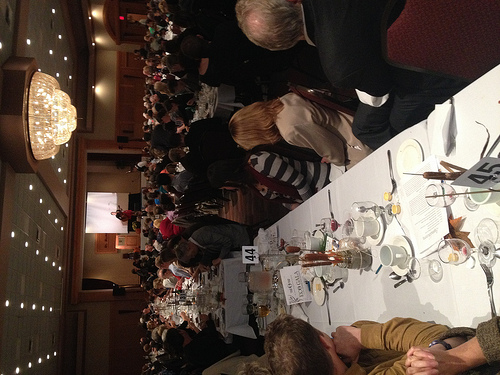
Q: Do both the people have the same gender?
A: No, they are both male and female.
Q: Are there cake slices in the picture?
A: No, there are no cake slices.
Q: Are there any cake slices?
A: No, there are no cake slices.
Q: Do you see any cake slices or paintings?
A: No, there are no cake slices or paintings.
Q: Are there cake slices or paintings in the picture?
A: No, there are no cake slices or paintings.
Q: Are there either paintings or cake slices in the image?
A: No, there are no cake slices or paintings.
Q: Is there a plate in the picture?
A: Yes, there is a plate.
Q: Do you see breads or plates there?
A: Yes, there is a plate.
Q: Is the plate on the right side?
A: Yes, the plate is on the right of the image.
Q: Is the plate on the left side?
A: No, the plate is on the right of the image.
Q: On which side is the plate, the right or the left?
A: The plate is on the right of the image.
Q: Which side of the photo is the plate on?
A: The plate is on the right of the image.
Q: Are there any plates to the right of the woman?
A: Yes, there is a plate to the right of the woman.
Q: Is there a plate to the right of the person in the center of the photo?
A: Yes, there is a plate to the right of the woman.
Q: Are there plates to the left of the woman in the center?
A: No, the plate is to the right of the woman.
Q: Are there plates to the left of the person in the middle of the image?
A: No, the plate is to the right of the woman.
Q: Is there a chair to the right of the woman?
A: No, there is a plate to the right of the woman.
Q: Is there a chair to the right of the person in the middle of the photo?
A: No, there is a plate to the right of the woman.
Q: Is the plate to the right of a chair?
A: No, the plate is to the right of the woman.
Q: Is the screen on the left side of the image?
A: Yes, the screen is on the left of the image.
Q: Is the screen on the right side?
A: No, the screen is on the left of the image.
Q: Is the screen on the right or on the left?
A: The screen is on the left of the image.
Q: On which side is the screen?
A: The screen is on the left of the image.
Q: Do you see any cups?
A: Yes, there is a cup.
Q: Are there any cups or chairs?
A: Yes, there is a cup.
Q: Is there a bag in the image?
A: No, there are no bags.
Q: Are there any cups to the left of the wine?
A: No, the cup is to the right of the wine.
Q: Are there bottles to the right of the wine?
A: No, there is a cup to the right of the wine.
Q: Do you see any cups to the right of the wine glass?
A: Yes, there is a cup to the right of the wine glass.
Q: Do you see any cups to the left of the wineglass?
A: No, the cup is to the right of the wineglass.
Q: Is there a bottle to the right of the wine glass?
A: No, there is a cup to the right of the wine glass.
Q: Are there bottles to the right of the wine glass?
A: No, there is a cup to the right of the wine glass.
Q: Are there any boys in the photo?
A: No, there are no boys.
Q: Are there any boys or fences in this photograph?
A: No, there are no boys or fences.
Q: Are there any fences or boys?
A: No, there are no boys or fences.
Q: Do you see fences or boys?
A: No, there are no boys or fences.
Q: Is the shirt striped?
A: Yes, the shirt is striped.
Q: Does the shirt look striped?
A: Yes, the shirt is striped.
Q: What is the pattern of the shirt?
A: The shirt is striped.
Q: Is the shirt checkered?
A: No, the shirt is striped.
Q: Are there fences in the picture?
A: No, there are no fences.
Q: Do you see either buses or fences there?
A: No, there are no fences or buses.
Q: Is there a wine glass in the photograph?
A: Yes, there is a wine glass.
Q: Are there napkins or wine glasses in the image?
A: Yes, there is a wine glass.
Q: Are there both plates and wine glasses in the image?
A: Yes, there are both a wine glass and a plate.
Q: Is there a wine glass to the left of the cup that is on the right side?
A: Yes, there is a wine glass to the left of the cup.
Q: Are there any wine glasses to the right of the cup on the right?
A: No, the wine glass is to the left of the cup.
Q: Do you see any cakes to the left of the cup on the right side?
A: No, there is a wine glass to the left of the cup.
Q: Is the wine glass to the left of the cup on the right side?
A: Yes, the wine glass is to the left of the cup.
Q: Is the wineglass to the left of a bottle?
A: No, the wineglass is to the left of the cup.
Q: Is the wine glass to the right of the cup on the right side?
A: No, the wine glass is to the left of the cup.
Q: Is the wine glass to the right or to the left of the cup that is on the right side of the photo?
A: The wine glass is to the left of the cup.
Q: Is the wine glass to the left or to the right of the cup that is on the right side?
A: The wine glass is to the left of the cup.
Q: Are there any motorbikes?
A: No, there are no motorbikes.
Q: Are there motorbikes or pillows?
A: No, there are no motorbikes or pillows.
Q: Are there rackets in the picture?
A: No, there are no rackets.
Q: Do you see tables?
A: Yes, there is a table.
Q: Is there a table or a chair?
A: Yes, there is a table.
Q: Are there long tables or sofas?
A: Yes, there is a long table.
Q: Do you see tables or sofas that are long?
A: Yes, the table is long.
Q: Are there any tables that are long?
A: Yes, there is a long table.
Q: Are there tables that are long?
A: Yes, there is a table that is long.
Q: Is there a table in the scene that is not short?
A: Yes, there is a long table.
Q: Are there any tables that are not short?
A: Yes, there is a long table.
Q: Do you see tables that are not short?
A: Yes, there is a long table.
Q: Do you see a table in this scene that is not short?
A: Yes, there is a long table.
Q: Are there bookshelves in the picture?
A: No, there are no bookshelves.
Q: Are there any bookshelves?
A: No, there are no bookshelves.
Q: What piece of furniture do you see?
A: The piece of furniture is a table.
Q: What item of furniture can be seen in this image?
A: The piece of furniture is a table.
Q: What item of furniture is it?
A: The piece of furniture is a table.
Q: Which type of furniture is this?
A: That is a table.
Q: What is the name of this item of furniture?
A: That is a table.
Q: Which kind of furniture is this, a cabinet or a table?
A: That is a table.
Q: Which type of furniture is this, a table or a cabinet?
A: That is a table.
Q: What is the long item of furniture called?
A: The piece of furniture is a table.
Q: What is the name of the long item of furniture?
A: The piece of furniture is a table.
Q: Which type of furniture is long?
A: The furniture is a table.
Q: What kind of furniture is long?
A: The furniture is a table.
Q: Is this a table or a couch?
A: This is a table.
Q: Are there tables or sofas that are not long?
A: No, there is a table but it is long.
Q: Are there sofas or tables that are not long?
A: No, there is a table but it is long.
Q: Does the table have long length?
A: Yes, the table is long.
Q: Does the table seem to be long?
A: Yes, the table is long.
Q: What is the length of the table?
A: The table is long.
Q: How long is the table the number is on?
A: The table is long.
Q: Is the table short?
A: No, the table is long.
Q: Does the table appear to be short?
A: No, the table is long.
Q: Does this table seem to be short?
A: No, the table is long.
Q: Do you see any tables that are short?
A: No, there is a table but it is long.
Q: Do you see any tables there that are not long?
A: No, there is a table but it is long.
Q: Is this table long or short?
A: The table is long.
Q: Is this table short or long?
A: The table is long.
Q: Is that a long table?
A: Yes, that is a long table.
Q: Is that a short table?
A: No, that is a long table.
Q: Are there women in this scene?
A: Yes, there is a woman.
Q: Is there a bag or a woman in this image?
A: Yes, there is a woman.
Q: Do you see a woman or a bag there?
A: Yes, there is a woman.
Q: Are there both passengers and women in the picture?
A: No, there is a woman but no passengers.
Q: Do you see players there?
A: No, there are no players.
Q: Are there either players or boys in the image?
A: No, there are no players or boys.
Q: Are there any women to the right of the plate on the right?
A: No, the woman is to the left of the plate.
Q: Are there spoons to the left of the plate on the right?
A: No, there is a woman to the left of the plate.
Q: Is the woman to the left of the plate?
A: Yes, the woman is to the left of the plate.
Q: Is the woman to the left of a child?
A: No, the woman is to the left of the plate.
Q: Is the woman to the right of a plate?
A: No, the woman is to the left of a plate.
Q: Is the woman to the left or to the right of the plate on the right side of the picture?
A: The woman is to the left of the plate.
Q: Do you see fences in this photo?
A: No, there are no fences.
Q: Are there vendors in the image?
A: No, there are no vendors.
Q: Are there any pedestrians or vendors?
A: No, there are no vendors or pedestrians.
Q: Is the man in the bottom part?
A: Yes, the man is in the bottom of the image.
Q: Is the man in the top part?
A: No, the man is in the bottom of the image.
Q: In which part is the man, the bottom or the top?
A: The man is in the bottom of the image.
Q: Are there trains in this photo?
A: No, there are no trains.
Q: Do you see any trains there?
A: No, there are no trains.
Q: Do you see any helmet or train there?
A: No, there are no trains or helmets.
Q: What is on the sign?
A: The number is on the sign.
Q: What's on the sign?
A: The number is on the sign.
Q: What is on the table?
A: The number is on the table.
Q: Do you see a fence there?
A: No, there are no fences.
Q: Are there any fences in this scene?
A: No, there are no fences.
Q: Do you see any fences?
A: No, there are no fences.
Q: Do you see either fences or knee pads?
A: No, there are no fences or knee pads.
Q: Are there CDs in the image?
A: No, there are no cds.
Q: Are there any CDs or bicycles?
A: No, there are no CDs or bicycles.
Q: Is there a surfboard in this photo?
A: No, there are no surfboards.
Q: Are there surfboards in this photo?
A: No, there are no surfboards.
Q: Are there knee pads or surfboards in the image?
A: No, there are no surfboards or knee pads.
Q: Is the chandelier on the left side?
A: Yes, the chandelier is on the left of the image.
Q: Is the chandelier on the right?
A: No, the chandelier is on the left of the image.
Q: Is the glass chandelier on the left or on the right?
A: The chandelier is on the left of the image.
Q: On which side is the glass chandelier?
A: The chandelier is on the left of the image.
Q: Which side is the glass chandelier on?
A: The chandelier is on the left of the image.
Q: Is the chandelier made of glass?
A: Yes, the chandelier is made of glass.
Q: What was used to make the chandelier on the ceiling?
A: The chandelier is made of glass.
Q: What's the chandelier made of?
A: The chandelier is made of glass.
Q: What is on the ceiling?
A: The chandelier is on the ceiling.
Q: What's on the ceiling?
A: The chandelier is on the ceiling.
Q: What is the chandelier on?
A: The chandelier is on the ceiling.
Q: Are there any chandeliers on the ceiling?
A: Yes, there is a chandelier on the ceiling.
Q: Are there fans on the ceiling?
A: No, there is a chandelier on the ceiling.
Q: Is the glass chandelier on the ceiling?
A: Yes, the chandelier is on the ceiling.